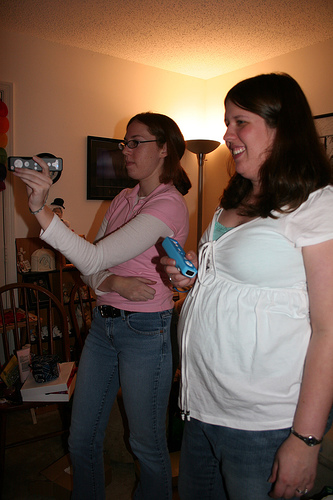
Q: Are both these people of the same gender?
A: Yes, all the people are female.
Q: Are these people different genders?
A: No, all the people are female.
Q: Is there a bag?
A: No, there are no bags.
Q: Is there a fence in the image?
A: No, there are no fences.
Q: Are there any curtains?
A: No, there are no curtains.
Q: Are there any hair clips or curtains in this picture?
A: No, there are no curtains or hair clips.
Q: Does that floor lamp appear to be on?
A: Yes, the floor lamp is on.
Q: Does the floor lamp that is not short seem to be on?
A: Yes, the floor lamp is on.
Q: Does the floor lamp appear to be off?
A: No, the floor lamp is on.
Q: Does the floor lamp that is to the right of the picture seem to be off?
A: No, the floor lamp is on.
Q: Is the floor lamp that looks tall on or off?
A: The floor lamp is on.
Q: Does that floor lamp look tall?
A: Yes, the floor lamp is tall.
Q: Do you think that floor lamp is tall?
A: Yes, the floor lamp is tall.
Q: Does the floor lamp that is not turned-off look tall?
A: Yes, the floor lamp is tall.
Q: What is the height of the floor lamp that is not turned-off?
A: The floor lamp is tall.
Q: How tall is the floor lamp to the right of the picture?
A: The floor lamp is tall.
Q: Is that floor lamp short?
A: No, the floor lamp is tall.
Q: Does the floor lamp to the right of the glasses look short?
A: No, the floor lamp is tall.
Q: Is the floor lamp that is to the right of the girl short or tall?
A: The floor lamp is tall.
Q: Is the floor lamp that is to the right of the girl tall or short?
A: The floor lamp is tall.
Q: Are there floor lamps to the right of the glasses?
A: Yes, there is a floor lamp to the right of the glasses.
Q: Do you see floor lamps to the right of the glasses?
A: Yes, there is a floor lamp to the right of the glasses.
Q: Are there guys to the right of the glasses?
A: No, there is a floor lamp to the right of the glasses.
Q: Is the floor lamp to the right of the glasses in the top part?
A: Yes, the floor lamp is to the right of the glasses.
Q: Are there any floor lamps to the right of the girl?
A: Yes, there is a floor lamp to the right of the girl.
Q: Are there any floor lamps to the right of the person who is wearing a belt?
A: Yes, there is a floor lamp to the right of the girl.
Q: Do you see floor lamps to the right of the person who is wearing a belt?
A: Yes, there is a floor lamp to the right of the girl.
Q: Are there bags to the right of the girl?
A: No, there is a floor lamp to the right of the girl.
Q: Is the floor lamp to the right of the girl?
A: Yes, the floor lamp is to the right of the girl.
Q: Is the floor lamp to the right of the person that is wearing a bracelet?
A: Yes, the floor lamp is to the right of the girl.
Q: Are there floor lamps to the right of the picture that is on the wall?
A: Yes, there is a floor lamp to the right of the picture.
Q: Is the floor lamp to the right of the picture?
A: Yes, the floor lamp is to the right of the picture.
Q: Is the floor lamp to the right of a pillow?
A: No, the floor lamp is to the right of the picture.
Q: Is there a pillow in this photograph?
A: No, there are no pillows.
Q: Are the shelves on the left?
A: Yes, the shelves are on the left of the image.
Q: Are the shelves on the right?
A: No, the shelves are on the left of the image.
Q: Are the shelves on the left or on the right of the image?
A: The shelves are on the left of the image.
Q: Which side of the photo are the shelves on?
A: The shelves are on the left of the image.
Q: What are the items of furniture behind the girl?
A: The pieces of furniture are shelves.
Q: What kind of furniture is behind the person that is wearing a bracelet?
A: The pieces of furniture are shelves.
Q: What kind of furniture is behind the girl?
A: The pieces of furniture are shelves.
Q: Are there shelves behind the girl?
A: Yes, there are shelves behind the girl.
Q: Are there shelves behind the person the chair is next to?
A: Yes, there are shelves behind the girl.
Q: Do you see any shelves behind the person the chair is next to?
A: Yes, there are shelves behind the girl.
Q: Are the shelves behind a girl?
A: Yes, the shelves are behind a girl.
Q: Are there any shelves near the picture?
A: Yes, there are shelves near the picture.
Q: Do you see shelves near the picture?
A: Yes, there are shelves near the picture.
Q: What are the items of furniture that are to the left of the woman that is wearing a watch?
A: The pieces of furniture are shelves.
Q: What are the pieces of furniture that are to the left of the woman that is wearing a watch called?
A: The pieces of furniture are shelves.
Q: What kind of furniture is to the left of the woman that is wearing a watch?
A: The pieces of furniture are shelves.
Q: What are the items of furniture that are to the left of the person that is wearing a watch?
A: The pieces of furniture are shelves.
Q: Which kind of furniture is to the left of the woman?
A: The pieces of furniture are shelves.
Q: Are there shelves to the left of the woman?
A: Yes, there are shelves to the left of the woman.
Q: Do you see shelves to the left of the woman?
A: Yes, there are shelves to the left of the woman.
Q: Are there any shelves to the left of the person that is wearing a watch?
A: Yes, there are shelves to the left of the woman.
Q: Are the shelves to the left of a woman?
A: Yes, the shelves are to the left of a woman.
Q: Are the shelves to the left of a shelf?
A: No, the shelves are to the left of a woman.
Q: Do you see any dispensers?
A: No, there are no dispensers.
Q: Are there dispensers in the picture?
A: No, there are no dispensers.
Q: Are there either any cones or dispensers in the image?
A: No, there are no dispensers or cones.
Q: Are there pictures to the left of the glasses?
A: Yes, there is a picture to the left of the glasses.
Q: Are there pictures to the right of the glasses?
A: No, the picture is to the left of the glasses.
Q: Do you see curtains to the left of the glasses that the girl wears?
A: No, there is a picture to the left of the glasses.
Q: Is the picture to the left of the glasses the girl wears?
A: Yes, the picture is to the left of the glasses.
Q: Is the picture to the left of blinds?
A: No, the picture is to the left of the glasses.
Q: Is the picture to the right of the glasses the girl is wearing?
A: No, the picture is to the left of the glasses.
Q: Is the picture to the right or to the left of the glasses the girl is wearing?
A: The picture is to the left of the glasses.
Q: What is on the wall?
A: The picture is on the wall.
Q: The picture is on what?
A: The picture is on the wall.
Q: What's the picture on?
A: The picture is on the wall.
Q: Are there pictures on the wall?
A: Yes, there is a picture on the wall.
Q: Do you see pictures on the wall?
A: Yes, there is a picture on the wall.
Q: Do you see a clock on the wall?
A: No, there is a picture on the wall.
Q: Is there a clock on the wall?
A: No, there is a picture on the wall.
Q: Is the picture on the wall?
A: Yes, the picture is on the wall.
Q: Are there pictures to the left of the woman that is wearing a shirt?
A: Yes, there is a picture to the left of the woman.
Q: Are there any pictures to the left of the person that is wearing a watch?
A: Yes, there is a picture to the left of the woman.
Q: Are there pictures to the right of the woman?
A: No, the picture is to the left of the woman.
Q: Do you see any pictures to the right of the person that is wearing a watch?
A: No, the picture is to the left of the woman.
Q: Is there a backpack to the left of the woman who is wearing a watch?
A: No, there is a picture to the left of the woman.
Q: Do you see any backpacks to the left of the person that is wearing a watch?
A: No, there is a picture to the left of the woman.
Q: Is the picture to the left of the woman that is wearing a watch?
A: Yes, the picture is to the left of the woman.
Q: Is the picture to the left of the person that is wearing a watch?
A: Yes, the picture is to the left of the woman.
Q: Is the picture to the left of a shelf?
A: No, the picture is to the left of the woman.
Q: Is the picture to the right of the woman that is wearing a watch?
A: No, the picture is to the left of the woman.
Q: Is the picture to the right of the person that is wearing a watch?
A: No, the picture is to the left of the woman.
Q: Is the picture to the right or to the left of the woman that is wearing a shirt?
A: The picture is to the left of the woman.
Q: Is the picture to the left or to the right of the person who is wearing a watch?
A: The picture is to the left of the woman.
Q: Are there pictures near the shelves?
A: Yes, there is a picture near the shelves.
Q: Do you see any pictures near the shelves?
A: Yes, there is a picture near the shelves.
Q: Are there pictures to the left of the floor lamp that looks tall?
A: Yes, there is a picture to the left of the floor lamp.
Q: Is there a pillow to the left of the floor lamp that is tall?
A: No, there is a picture to the left of the floor lamp.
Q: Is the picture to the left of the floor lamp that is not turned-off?
A: Yes, the picture is to the left of the floor lamp.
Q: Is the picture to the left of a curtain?
A: No, the picture is to the left of the floor lamp.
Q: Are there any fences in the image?
A: No, there are no fences.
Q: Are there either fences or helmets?
A: No, there are no fences or helmets.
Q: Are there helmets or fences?
A: No, there are no fences or helmets.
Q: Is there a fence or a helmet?
A: No, there are no fences or helmets.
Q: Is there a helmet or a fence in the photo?
A: No, there are no fences or helmets.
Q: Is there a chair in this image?
A: Yes, there is a chair.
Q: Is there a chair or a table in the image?
A: Yes, there is a chair.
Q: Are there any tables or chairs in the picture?
A: Yes, there is a chair.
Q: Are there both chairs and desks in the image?
A: No, there is a chair but no desks.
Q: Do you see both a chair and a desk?
A: No, there is a chair but no desks.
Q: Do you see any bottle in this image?
A: No, there are no bottles.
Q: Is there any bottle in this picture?
A: No, there are no bottles.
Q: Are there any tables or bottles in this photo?
A: No, there are no bottles or tables.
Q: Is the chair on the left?
A: Yes, the chair is on the left of the image.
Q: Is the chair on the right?
A: No, the chair is on the left of the image.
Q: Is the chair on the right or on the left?
A: The chair is on the left of the image.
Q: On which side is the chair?
A: The chair is on the left of the image.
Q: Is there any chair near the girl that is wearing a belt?
A: Yes, there is a chair near the girl.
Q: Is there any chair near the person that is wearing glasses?
A: Yes, there is a chair near the girl.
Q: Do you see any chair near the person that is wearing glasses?
A: Yes, there is a chair near the girl.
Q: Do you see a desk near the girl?
A: No, there is a chair near the girl.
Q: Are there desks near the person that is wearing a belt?
A: No, there is a chair near the girl.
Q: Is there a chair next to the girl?
A: Yes, there is a chair next to the girl.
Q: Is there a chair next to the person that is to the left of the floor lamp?
A: Yes, there is a chair next to the girl.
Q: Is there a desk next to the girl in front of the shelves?
A: No, there is a chair next to the girl.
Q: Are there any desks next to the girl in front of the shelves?
A: No, there is a chair next to the girl.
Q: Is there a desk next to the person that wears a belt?
A: No, there is a chair next to the girl.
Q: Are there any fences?
A: No, there are no fences.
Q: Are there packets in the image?
A: No, there are no packets.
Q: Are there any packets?
A: No, there are no packets.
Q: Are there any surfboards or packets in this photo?
A: No, there are no packets or surfboards.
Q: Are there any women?
A: Yes, there is a woman.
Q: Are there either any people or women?
A: Yes, there is a woman.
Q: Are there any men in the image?
A: No, there are no men.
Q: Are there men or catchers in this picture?
A: No, there are no men or catchers.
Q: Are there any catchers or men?
A: No, there are no men or catchers.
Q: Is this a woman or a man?
A: This is a woman.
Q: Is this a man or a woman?
A: This is a woman.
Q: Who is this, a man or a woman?
A: This is a woman.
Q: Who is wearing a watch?
A: The woman is wearing a watch.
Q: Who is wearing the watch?
A: The woman is wearing a watch.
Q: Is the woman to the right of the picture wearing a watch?
A: Yes, the woman is wearing a watch.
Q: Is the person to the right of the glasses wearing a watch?
A: Yes, the woman is wearing a watch.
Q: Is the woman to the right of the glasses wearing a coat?
A: No, the woman is wearing a watch.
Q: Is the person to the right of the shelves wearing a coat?
A: No, the woman is wearing a watch.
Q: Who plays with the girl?
A: The woman plays with the girl.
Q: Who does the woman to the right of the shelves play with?
A: The woman plays with the girl.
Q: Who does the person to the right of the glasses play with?
A: The woman plays with the girl.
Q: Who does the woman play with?
A: The woman plays with the girl.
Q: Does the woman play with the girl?
A: Yes, the woman plays with the girl.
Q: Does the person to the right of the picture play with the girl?
A: Yes, the woman plays with the girl.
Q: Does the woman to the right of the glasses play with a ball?
A: No, the woman plays with the girl.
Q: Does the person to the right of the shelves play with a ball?
A: No, the woman plays with the girl.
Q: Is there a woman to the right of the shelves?
A: Yes, there is a woman to the right of the shelves.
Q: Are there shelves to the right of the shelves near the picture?
A: No, there is a woman to the right of the shelves.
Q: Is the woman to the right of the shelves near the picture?
A: Yes, the woman is to the right of the shelves.